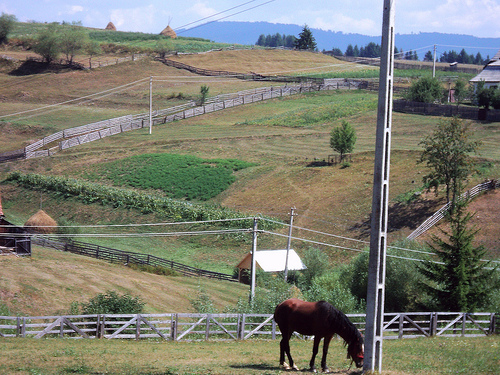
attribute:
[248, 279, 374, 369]
horse — brown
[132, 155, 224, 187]
grass — green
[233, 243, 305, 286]
house — small